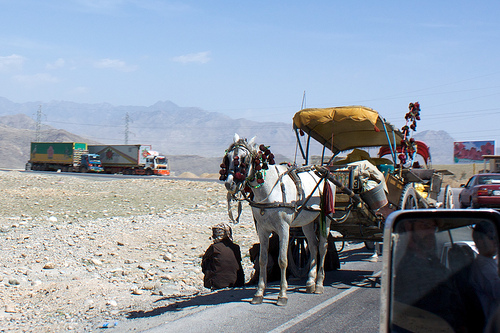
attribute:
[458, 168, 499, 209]
car — Red 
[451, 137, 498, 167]
billboard — large 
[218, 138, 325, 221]
straps — black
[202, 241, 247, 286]
shirt — brown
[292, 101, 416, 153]
covering — brown